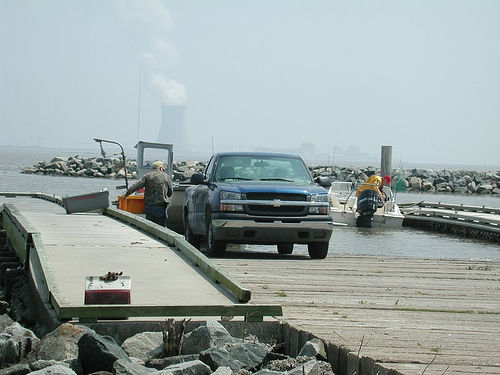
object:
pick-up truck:
[182, 150, 333, 260]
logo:
[265, 196, 288, 209]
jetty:
[73, 157, 144, 180]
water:
[347, 226, 372, 248]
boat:
[327, 172, 409, 229]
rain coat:
[355, 174, 381, 198]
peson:
[353, 167, 386, 217]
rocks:
[450, 170, 496, 194]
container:
[58, 188, 108, 217]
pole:
[372, 144, 399, 194]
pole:
[92, 134, 129, 184]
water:
[372, 229, 428, 259]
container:
[117, 194, 147, 215]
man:
[123, 160, 174, 225]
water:
[332, 240, 343, 249]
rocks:
[22, 152, 57, 179]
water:
[32, 169, 64, 189]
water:
[4, 153, 17, 166]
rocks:
[170, 158, 199, 179]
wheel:
[205, 224, 229, 254]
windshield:
[215, 153, 315, 185]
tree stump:
[160, 316, 193, 356]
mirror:
[252, 159, 272, 168]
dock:
[399, 201, 498, 241]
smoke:
[111, 0, 190, 103]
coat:
[354, 176, 380, 195]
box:
[82, 275, 132, 319]